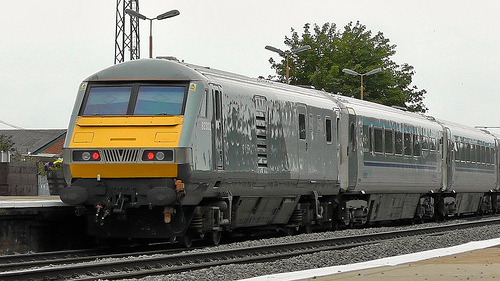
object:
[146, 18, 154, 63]
pole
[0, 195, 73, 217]
dock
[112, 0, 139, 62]
tower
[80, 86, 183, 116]
front windows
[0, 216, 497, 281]
tracks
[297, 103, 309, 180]
door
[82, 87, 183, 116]
windshield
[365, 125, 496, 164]
window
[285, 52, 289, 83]
post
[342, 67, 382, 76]
lights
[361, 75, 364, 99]
post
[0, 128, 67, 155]
roof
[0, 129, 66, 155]
building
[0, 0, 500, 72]
sky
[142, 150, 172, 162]
light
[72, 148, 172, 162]
signals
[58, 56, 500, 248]
engine car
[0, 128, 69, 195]
build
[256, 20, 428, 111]
trees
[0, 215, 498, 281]
ground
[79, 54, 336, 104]
top